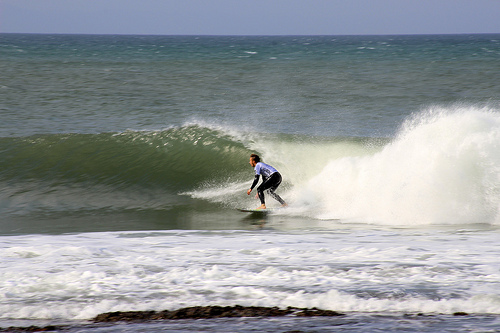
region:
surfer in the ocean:
[232, 146, 309, 223]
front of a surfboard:
[231, 203, 261, 221]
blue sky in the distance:
[13, 0, 478, 29]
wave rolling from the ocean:
[135, 116, 251, 199]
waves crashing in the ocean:
[381, 95, 496, 229]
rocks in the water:
[95, 305, 312, 326]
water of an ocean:
[11, 35, 381, 100]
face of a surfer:
[242, 150, 264, 167]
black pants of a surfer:
[256, 172, 285, 202]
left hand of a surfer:
[244, 186, 254, 197]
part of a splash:
[425, 165, 459, 192]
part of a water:
[226, 255, 278, 304]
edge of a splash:
[357, 191, 413, 221]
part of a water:
[126, 180, 183, 217]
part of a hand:
[237, 180, 257, 200]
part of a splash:
[388, 148, 431, 168]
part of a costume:
[264, 168, 282, 181]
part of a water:
[275, 275, 335, 308]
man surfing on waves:
[228, 150, 280, 227]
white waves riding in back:
[335, 150, 460, 221]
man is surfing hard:
[226, 140, 326, 221]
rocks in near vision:
[75, 278, 341, 328]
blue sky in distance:
[36, 11, 406, 26]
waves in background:
[46, 40, 407, 101]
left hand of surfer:
[216, 171, 256, 196]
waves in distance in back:
[133, 46, 319, 111]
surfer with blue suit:
[226, 138, 316, 223]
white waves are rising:
[379, 105, 489, 216]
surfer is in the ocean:
[231, 151, 299, 216]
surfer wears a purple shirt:
[234, 151, 295, 221]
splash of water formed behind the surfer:
[301, 96, 498, 244]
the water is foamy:
[7, 227, 498, 322]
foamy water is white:
[5, 225, 497, 316]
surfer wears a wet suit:
[237, 148, 295, 215]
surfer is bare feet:
[238, 143, 291, 216]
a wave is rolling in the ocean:
[9, 111, 245, 190]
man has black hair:
[241, 145, 299, 213]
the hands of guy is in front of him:
[239, 148, 291, 219]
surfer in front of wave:
[225, 145, 297, 217]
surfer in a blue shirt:
[219, 148, 303, 223]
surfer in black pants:
[232, 145, 293, 222]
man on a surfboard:
[227, 150, 299, 221]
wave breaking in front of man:
[2, 117, 276, 197]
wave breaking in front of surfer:
[1, 116, 272, 190]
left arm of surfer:
[245, 167, 260, 192]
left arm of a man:
[246, 165, 262, 197]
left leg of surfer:
[253, 177, 277, 213]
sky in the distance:
[1, 1, 498, 33]